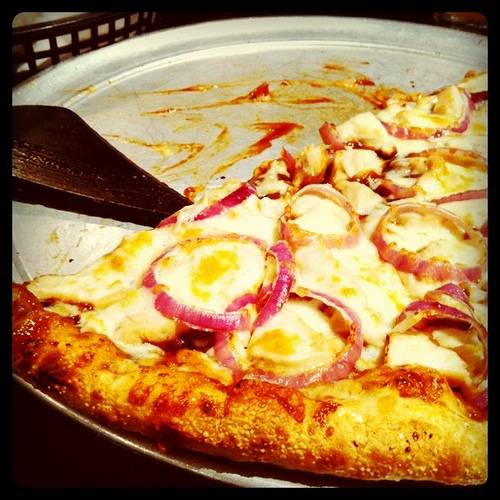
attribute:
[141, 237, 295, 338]
red onion — ring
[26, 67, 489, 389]
cheese — white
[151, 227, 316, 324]
onion — sliced, purple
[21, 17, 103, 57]
basket — brown, plastic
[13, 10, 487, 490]
pan — metal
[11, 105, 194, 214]
pizza server — overturned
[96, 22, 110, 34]
hole — square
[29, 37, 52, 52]
hole — square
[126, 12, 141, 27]
hole — square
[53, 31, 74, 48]
hole — square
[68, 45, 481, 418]
mozzarella — melted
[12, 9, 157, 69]
paper — white